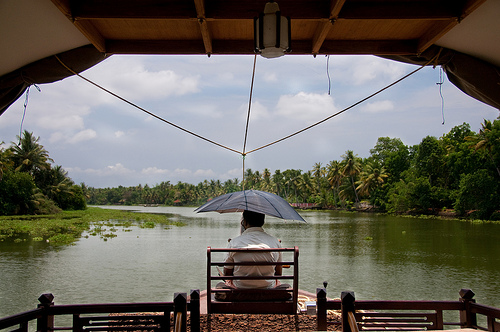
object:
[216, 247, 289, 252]
part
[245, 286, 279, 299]
part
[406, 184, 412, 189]
leaf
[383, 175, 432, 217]
bush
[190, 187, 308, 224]
umbrella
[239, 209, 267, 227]
head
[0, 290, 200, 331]
railings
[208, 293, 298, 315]
seat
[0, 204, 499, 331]
water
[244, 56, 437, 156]
ropes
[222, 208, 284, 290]
man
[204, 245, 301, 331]
chair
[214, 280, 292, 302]
cushion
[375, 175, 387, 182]
woods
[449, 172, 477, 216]
tree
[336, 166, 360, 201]
tree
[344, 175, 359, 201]
woods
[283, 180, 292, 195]
woods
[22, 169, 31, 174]
leaf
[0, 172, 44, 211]
plant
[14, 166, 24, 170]
leaf